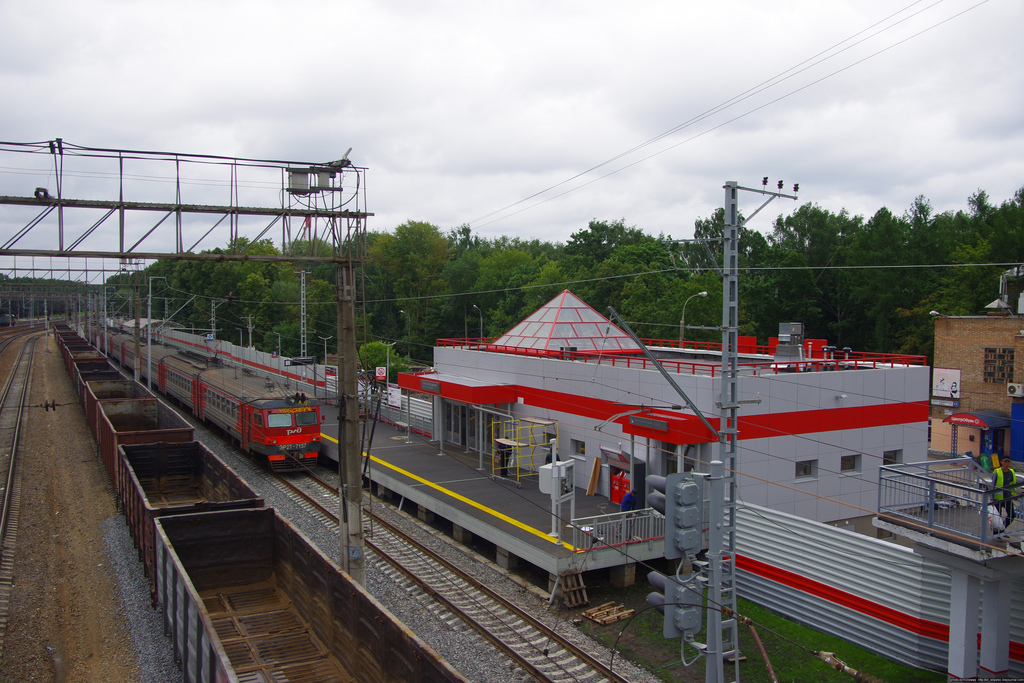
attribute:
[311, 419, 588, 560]
yellow line — straight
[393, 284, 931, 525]
train station — red and grey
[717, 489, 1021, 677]
metal fence — grey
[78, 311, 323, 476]
train — red and silver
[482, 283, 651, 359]
pyramid roof — Pyramid shaped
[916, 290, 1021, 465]
building — grey and red